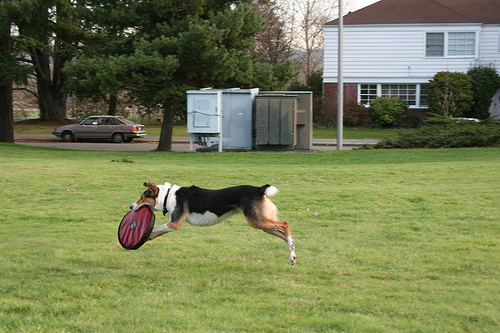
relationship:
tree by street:
[138, 78, 179, 175] [14, 135, 381, 152]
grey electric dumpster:
[230, 87, 319, 161] [186, 87, 261, 153]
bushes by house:
[368, 86, 485, 130] [333, 14, 500, 77]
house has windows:
[333, 14, 500, 77] [423, 33, 480, 59]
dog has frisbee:
[133, 169, 315, 265] [124, 206, 157, 247]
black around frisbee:
[143, 218, 151, 249] [124, 206, 157, 247]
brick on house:
[330, 79, 337, 115] [333, 14, 500, 77]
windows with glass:
[423, 33, 480, 59] [455, 42, 462, 52]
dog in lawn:
[133, 169, 315, 265] [0, 143, 500, 333]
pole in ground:
[337, 8, 349, 162] [317, 146, 368, 150]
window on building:
[20, 54, 33, 71] [8, 36, 162, 118]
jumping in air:
[82, 105, 321, 253] [172, 163, 251, 167]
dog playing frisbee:
[133, 169, 315, 265] [124, 206, 157, 247]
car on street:
[58, 114, 146, 139] [36, 135, 141, 152]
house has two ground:
[333, 14, 500, 77] [0, 119, 500, 333]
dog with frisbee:
[133, 169, 315, 265] [124, 206, 157, 247]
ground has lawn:
[59, 171, 104, 260] [0, 143, 500, 333]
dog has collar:
[133, 169, 315, 265] [160, 192, 171, 211]